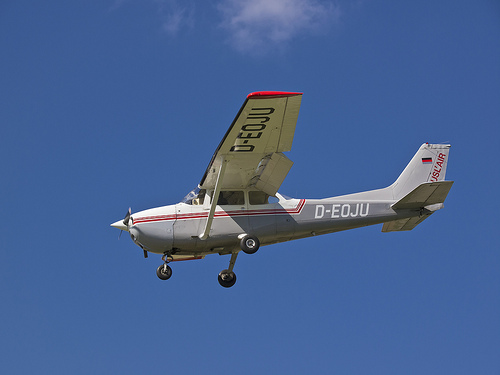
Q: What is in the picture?
A: An airplane.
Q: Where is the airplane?
A: In the air.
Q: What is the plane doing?
A: Flying.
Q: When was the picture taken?
A: Daytime.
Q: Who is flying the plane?
A: A pilot.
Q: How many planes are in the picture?
A: One.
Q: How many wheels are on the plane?
A: Three.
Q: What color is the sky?
A: Blue.